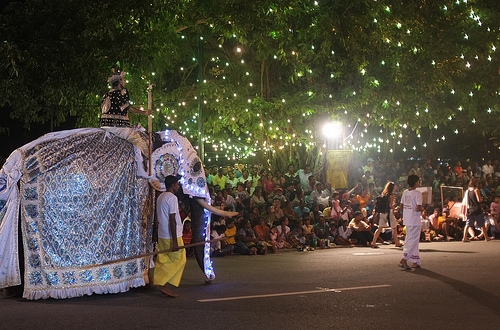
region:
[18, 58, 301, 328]
an elephant with a costume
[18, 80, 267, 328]
a costume on an elephant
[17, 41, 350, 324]
a person riding an elephant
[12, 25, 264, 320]
a person on an elephant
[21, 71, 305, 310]
a person standing on an elephant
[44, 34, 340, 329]
an elephant walking on the road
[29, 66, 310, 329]
an elephant walking on the street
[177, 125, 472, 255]
people sitting next to the street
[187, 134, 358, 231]
people sitting next to the road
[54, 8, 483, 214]
lights in the tree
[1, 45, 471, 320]
The elephant is walking down the street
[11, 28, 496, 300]
The people are in a parade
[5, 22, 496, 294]
People are watching the parade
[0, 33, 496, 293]
The people are enjoying the elephant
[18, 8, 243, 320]
The elephant is wearing a costume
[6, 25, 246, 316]
Someone is sitting on the elephant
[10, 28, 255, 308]
The elephant is entertaining people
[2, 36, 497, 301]
The elephant is following someone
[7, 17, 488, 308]
People are enjoying their evening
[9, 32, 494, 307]
The people are out at night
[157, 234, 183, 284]
a man in a yellow pant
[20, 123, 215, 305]
a dressed elephant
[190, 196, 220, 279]
the elephant's trunk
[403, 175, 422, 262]
a woman walking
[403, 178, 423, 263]
a woman in a white dress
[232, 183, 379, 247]
a lot of people watching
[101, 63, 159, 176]
a man on the elephant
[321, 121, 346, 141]
a very potent light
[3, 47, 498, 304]
a show in the middle of the night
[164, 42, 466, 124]
several big tree branches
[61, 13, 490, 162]
The lights are in the trees.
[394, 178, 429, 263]
The woman is wearing white.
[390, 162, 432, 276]
The woman is walking.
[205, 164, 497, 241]
The people are sitting.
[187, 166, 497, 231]
The people are watching.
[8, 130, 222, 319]
The elephant has a blanket.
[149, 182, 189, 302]
The man is walking.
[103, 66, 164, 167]
They are sitting on the elephant.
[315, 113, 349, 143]
The light is on.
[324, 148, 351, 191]
The sign is yellow.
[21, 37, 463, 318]
Elephant walking in parade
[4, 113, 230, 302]
Costume draping parade elephant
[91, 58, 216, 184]
Handler with rod atop elephant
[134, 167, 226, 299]
Handler with rod walking beside elephant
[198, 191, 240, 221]
White ivory elephant tusk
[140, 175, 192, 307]
Barefoot man in white shirt and yellow bottoms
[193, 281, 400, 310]
White lane stripe on pavement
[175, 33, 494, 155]
Lights hanging down from tree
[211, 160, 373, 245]
Spectators lining parade route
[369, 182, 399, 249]
Young girl with black backpack